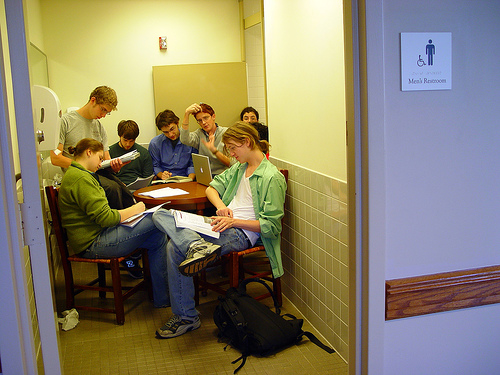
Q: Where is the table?
A: In the bathroom.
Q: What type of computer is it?
A: Mac.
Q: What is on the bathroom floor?
A: A Backpack.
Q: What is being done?
A: Studying.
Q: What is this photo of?
A: A group of people.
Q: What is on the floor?
A: A bag.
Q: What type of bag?
A: A bookbag.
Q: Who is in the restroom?
A: Students.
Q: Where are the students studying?
A: The Restroom.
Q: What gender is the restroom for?
A: Men.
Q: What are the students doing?
A: Studying.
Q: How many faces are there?
A: Seven.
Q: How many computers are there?
A: One.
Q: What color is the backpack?
A: One.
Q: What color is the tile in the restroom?
A: Tan.